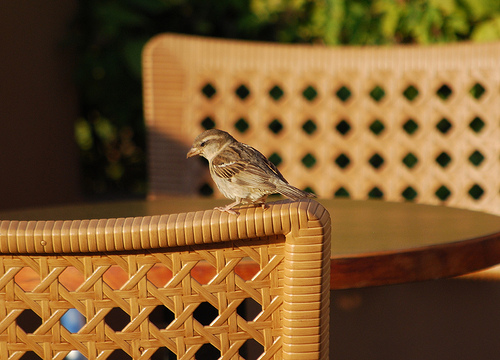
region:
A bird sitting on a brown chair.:
[153, 136, 343, 275]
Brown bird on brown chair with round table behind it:
[167, 116, 491, 295]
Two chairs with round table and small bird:
[68, 33, 489, 326]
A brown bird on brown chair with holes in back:
[129, 98, 354, 318]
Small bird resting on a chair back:
[167, 119, 495, 319]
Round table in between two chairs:
[8, 161, 495, 284]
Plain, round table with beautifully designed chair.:
[31, 200, 478, 326]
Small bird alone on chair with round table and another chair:
[118, 97, 499, 328]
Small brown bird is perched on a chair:
[155, 126, 373, 269]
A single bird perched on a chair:
[159, 107, 345, 287]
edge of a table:
[386, 255, 422, 270]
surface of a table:
[354, 210, 381, 242]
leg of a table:
[214, 204, 239, 220]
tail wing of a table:
[278, 182, 313, 201]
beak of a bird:
[182, 145, 195, 161]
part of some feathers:
[227, 166, 260, 191]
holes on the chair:
[118, 264, 248, 341]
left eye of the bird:
[199, 138, 208, 148]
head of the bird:
[198, 127, 218, 138]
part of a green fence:
[281, 11, 342, 33]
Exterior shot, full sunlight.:
[6, 0, 492, 355]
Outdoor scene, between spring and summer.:
[5, 21, 499, 359]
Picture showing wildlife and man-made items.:
[10, 5, 490, 350]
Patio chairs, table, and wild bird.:
[35, 48, 491, 334]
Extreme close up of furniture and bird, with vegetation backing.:
[0, 5, 495, 355]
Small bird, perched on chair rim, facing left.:
[185, 125, 305, 215]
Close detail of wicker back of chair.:
[5, 218, 330, 358]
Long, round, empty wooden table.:
[80, 183, 485, 285]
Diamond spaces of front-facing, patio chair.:
[193, 50, 498, 183]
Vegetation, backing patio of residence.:
[14, 21, 498, 168]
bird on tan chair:
[183, 126, 303, 218]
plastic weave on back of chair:
[206, 277, 241, 307]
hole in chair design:
[191, 298, 221, 328]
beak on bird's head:
[178, 144, 204, 165]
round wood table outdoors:
[353, 187, 475, 292]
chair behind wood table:
[122, 38, 450, 190]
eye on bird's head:
[196, 138, 213, 150]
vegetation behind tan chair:
[333, 20, 440, 45]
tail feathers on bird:
[276, 179, 313, 206]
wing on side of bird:
[210, 158, 265, 192]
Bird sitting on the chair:
[156, 130, 436, 266]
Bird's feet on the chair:
[183, 126, 375, 236]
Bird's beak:
[177, 129, 199, 158]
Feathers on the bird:
[193, 142, 310, 219]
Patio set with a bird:
[86, 172, 490, 307]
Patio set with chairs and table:
[135, 150, 480, 325]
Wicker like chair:
[61, 198, 275, 353]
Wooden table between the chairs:
[86, 207, 461, 297]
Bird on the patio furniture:
[179, 131, 384, 256]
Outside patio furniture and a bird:
[88, 135, 423, 280]